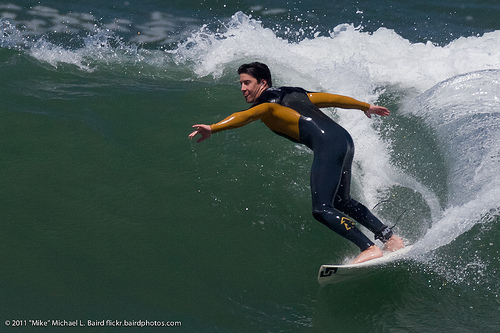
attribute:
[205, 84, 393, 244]
wetsuit — black 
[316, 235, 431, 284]
surfboard — white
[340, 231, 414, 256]
feet — bare